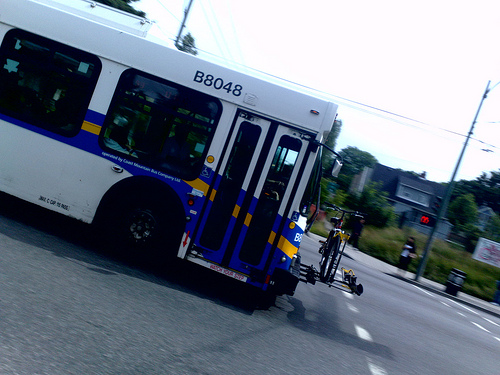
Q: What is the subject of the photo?
A: Bus.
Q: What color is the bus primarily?
A: White.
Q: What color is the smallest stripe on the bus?
A: Yellow.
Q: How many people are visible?
A: One.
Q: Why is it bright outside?
A: It's daytime.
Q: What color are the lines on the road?
A: White.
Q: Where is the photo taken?
A: Street.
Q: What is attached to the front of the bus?
A: Bikes.